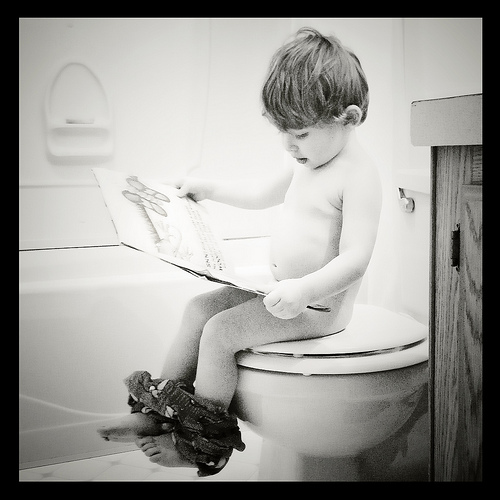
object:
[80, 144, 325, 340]
book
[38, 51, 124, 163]
container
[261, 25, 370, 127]
hair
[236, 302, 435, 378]
lid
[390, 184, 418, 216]
handle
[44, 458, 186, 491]
floor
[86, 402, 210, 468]
feet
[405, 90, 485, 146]
counter top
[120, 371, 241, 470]
pajama pants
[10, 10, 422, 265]
wall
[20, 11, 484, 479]
toilet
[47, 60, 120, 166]
tub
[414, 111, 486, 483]
cabinet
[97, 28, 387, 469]
boy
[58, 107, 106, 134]
soap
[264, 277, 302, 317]
hand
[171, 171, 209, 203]
hand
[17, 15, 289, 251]
shower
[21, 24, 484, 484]
bathroom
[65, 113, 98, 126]
soap bar